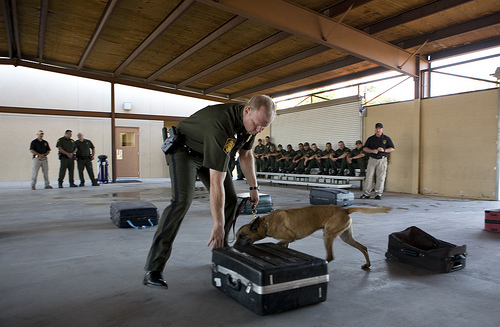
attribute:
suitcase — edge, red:
[479, 204, 498, 234]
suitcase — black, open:
[384, 224, 469, 274]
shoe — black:
[141, 265, 169, 287]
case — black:
[207, 240, 331, 312]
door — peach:
[112, 125, 139, 181]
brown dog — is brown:
[231, 200, 391, 292]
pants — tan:
[30, 160, 52, 187]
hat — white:
[37, 128, 44, 137]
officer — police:
[144, 95, 276, 289]